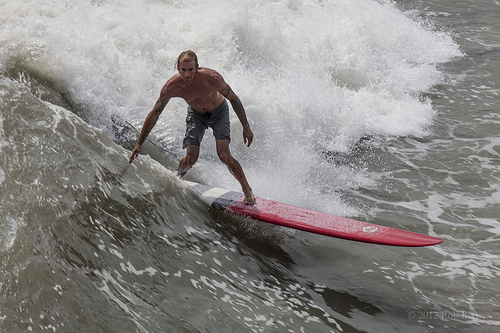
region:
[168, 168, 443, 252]
A long red, black, and white surfboard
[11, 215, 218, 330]
A dark body of water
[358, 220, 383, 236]
The logo on the end of a surfboard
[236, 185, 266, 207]
A foot standing on a surfboard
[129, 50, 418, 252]
A man standing on a surfboard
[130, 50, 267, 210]
A man wearing gray shorts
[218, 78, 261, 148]
The tattooed arm of a man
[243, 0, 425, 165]
The white crash of a wave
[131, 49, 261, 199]
A man wet from water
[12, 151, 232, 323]
The rise of a wave in the water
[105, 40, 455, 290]
Man on a surfboard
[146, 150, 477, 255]
Red and white surfboard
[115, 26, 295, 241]
Man wearing shorts on a surfboard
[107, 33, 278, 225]
Man standing on a surfboard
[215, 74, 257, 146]
Tattoos on a man's arm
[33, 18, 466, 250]
Large wave in the ocean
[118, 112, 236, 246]
Surfboard in the water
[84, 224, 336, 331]
Foam in the water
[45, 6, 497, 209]
Crashing wave in the ocean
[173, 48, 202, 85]
the head of a person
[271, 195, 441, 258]
a red surf board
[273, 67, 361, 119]
splashing water from a wave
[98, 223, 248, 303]
a wave in the water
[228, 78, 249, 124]
an arm of a person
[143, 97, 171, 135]
an arm of a person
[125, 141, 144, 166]
a hand of a person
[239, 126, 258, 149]
a hand of a person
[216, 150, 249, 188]
the leg of a person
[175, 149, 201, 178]
the leg of a person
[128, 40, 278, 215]
Man on surf board touching large wave.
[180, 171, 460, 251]
Red, white and blue surf long-board.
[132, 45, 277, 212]
Shirtless man in shorts on a surf board.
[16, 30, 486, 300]
Large, crashing green-water wave.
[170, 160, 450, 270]
Surf board tip out of water of wave.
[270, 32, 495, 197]
Foamy water ahead of crashing wave.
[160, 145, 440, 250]
Bare feet on surf board.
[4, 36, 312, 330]
Man surfing on very high wave nearing shore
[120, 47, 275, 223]
Man in board-shorts in surfing stance.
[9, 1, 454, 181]
Man in shorts standing amid mighty crashing waves.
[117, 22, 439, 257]
blonde haired surfer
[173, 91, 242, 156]
grey swim trunk on surfer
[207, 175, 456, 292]
red tipped surf board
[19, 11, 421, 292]
rolling wave in ocean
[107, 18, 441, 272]
surfer on red,white, and black surf board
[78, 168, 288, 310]
bubbles in water near wave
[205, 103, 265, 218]
left leg of surfer, surfing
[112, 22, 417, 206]
crashing wave with a surfer riding it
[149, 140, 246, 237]
white with black striped half of a surf board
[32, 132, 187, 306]
ripples in ocean water near wave